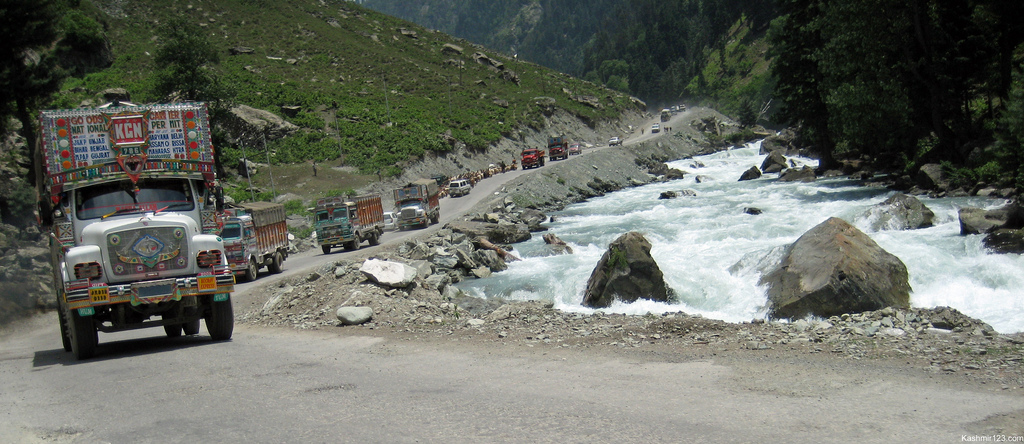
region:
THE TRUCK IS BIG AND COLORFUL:
[19, 77, 258, 365]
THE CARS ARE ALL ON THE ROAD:
[38, 90, 590, 347]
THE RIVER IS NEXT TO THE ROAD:
[419, 103, 1018, 364]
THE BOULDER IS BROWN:
[743, 209, 922, 333]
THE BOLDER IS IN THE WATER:
[746, 213, 914, 328]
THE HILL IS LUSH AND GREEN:
[0, 11, 662, 242]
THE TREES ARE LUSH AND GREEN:
[729, 7, 1018, 207]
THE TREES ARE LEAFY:
[728, 4, 1017, 194]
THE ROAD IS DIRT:
[26, 89, 1009, 440]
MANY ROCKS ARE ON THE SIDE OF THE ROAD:
[311, 181, 593, 352]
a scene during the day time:
[2, 3, 1021, 434]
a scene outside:
[5, 6, 1021, 440]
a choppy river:
[403, 104, 1020, 387]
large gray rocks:
[577, 107, 1011, 338]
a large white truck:
[11, 83, 287, 375]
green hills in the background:
[11, 10, 1020, 277]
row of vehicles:
[16, 85, 655, 377]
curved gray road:
[0, 104, 1006, 440]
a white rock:
[349, 247, 429, 290]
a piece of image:
[739, 383, 752, 396]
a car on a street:
[41, 169, 242, 343]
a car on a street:
[210, 199, 290, 285]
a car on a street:
[386, 171, 444, 228]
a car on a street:
[459, 168, 475, 185]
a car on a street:
[481, 158, 500, 177]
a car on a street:
[502, 146, 521, 175]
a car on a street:
[566, 136, 585, 160]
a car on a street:
[607, 130, 624, 147]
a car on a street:
[654, 99, 677, 126]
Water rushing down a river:
[456, 120, 1017, 352]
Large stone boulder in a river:
[717, 215, 914, 324]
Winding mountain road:
[1, 104, 1014, 437]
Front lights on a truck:
[70, 245, 225, 284]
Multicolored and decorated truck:
[35, 96, 238, 356]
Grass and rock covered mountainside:
[0, 11, 658, 322]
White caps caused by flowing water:
[452, 123, 1019, 336]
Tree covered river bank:
[601, 3, 1023, 196]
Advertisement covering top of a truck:
[35, 91, 220, 197]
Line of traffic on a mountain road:
[28, 75, 706, 380]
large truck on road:
[17, 60, 227, 321]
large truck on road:
[220, 186, 296, 270]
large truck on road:
[326, 174, 374, 247]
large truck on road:
[371, 151, 438, 241]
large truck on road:
[485, 127, 542, 216]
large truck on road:
[536, 100, 587, 158]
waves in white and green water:
[661, 192, 710, 212]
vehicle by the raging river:
[21, 103, 256, 359]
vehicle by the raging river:
[212, 191, 296, 296]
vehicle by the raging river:
[310, 191, 386, 250]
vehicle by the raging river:
[384, 175, 441, 224]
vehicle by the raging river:
[446, 172, 478, 198]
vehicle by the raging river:
[459, 163, 483, 190]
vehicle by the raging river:
[473, 157, 493, 171]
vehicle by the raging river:
[513, 141, 548, 170]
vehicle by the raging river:
[542, 134, 566, 163]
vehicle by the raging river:
[655, 101, 671, 120]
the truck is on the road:
[35, 102, 241, 347]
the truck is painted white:
[66, 181, 232, 303]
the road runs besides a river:
[6, 82, 1018, 433]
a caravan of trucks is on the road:
[43, 95, 616, 368]